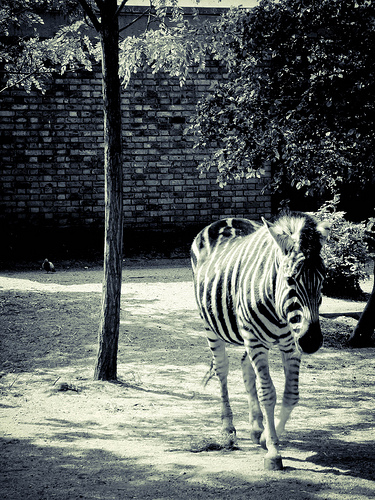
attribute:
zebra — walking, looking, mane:
[186, 208, 354, 351]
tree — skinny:
[73, 101, 155, 213]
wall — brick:
[142, 114, 164, 154]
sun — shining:
[39, 3, 197, 63]